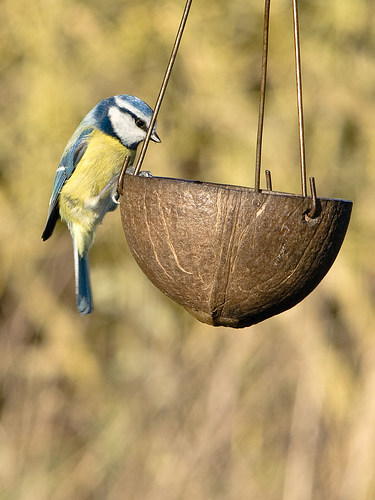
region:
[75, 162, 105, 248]
This bird has a yellow breast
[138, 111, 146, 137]
This bird has a black eye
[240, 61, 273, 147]
There are metal hangers visible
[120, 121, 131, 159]
This bird has a white face here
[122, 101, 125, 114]
There is a blue line visible on the bird's face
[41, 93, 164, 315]
Colorful bird perched on feeder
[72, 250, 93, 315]
Long blue tail on bird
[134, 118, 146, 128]
Small dark eye on bird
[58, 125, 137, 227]
Yellow stomach on colorful bird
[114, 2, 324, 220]
Three metal hangers on birdfeeder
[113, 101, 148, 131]
Thin black stripe on bird's head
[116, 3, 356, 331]
Brown birdfeeder shaped like half a nut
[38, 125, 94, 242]
One blue and white wing on bird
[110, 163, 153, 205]
Bird's feet hanging onto feeder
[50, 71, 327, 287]
a bird is standing on a pot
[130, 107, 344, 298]
the pot is metallic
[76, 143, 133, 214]
bird is yellow in color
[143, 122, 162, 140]
beak is b;ack in color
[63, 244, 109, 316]
tail is black in color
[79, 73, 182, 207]
bird is looking into the pot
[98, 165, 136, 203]
legs are brown in color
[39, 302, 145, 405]
plants are seen at the background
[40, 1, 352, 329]
The bird is on a feeder.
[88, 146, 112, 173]
The bird is yellow.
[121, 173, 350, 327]
The feeder is bowl shaped.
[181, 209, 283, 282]
The feeder is brown.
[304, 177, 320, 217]
The holder is hooked into the feeder.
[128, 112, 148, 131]
The bird is looking into the feeder.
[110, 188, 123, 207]
The bird's feed grip the feeder.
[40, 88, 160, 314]
bird perched on an object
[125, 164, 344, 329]
bowl attached to swing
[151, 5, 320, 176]
poles from which bowl hangs from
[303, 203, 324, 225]
hole in the bowl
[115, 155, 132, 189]
hook near the bird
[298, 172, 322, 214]
hook far from bird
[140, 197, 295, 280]
texture on the bowl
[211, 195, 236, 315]
thick patch down the center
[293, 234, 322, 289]
lines in the bowl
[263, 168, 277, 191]
hook behind the view